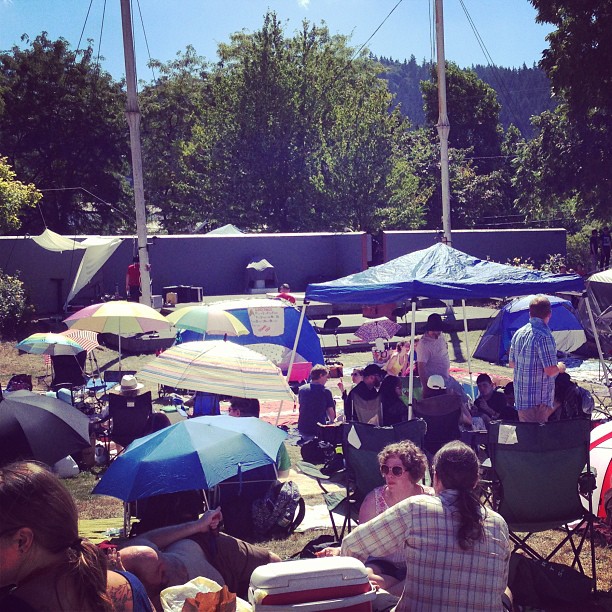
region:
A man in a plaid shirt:
[336, 436, 538, 610]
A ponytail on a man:
[452, 468, 485, 549]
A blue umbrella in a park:
[91, 411, 288, 522]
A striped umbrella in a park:
[124, 334, 300, 428]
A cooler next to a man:
[247, 557, 379, 610]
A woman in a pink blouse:
[351, 441, 433, 524]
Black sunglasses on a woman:
[378, 461, 404, 475]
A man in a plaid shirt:
[508, 295, 569, 433]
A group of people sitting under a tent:
[284, 245, 610, 456]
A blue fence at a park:
[3, 218, 603, 302]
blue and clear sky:
[339, 6, 482, 58]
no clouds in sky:
[143, 2, 228, 36]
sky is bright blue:
[138, 1, 251, 41]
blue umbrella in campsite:
[115, 412, 321, 515]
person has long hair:
[423, 403, 501, 562]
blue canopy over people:
[304, 223, 545, 401]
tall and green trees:
[3, 44, 513, 252]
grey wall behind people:
[24, 203, 571, 302]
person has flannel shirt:
[395, 485, 522, 609]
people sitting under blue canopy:
[293, 347, 509, 478]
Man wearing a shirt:
[337, 478, 518, 610]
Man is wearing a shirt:
[337, 482, 526, 610]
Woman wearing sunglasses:
[377, 457, 417, 479]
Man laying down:
[101, 502, 288, 605]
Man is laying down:
[95, 507, 294, 611]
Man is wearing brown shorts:
[189, 524, 288, 608]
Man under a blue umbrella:
[91, 410, 305, 610]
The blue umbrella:
[91, 410, 294, 500]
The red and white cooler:
[238, 551, 384, 608]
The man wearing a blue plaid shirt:
[503, 291, 574, 417]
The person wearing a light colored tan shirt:
[349, 441, 515, 605]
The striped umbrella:
[136, 335, 304, 410]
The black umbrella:
[0, 381, 106, 468]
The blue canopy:
[302, 247, 589, 299]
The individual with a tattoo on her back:
[0, 454, 151, 605]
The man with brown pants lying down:
[117, 524, 287, 589]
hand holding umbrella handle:
[174, 502, 246, 531]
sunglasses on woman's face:
[371, 451, 415, 483]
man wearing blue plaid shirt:
[490, 315, 581, 412]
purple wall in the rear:
[166, 225, 381, 299]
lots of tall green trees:
[75, 18, 514, 208]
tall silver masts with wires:
[103, 9, 187, 280]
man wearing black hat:
[407, 311, 466, 343]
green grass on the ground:
[0, 346, 45, 367]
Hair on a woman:
[375, 440, 425, 481]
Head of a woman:
[377, 440, 426, 495]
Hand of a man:
[198, 503, 225, 534]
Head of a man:
[114, 541, 175, 593]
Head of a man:
[427, 442, 482, 498]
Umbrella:
[131, 338, 300, 415]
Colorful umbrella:
[137, 332, 297, 415]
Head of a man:
[526, 294, 555, 325]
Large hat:
[420, 313, 455, 332]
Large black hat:
[419, 308, 459, 335]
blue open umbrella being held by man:
[90, 415, 290, 500]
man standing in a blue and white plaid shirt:
[506, 296, 569, 431]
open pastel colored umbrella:
[166, 303, 252, 342]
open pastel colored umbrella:
[63, 301, 174, 342]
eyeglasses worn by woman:
[374, 458, 413, 480]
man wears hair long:
[426, 439, 490, 548]